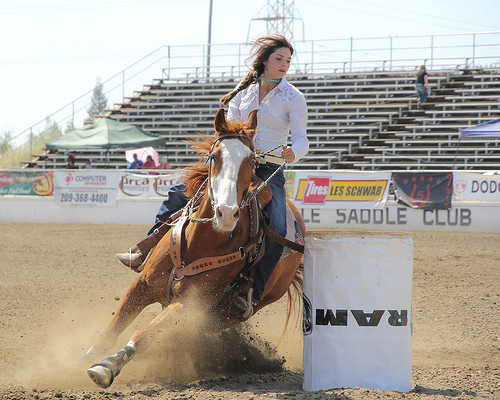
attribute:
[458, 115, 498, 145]
tent — blue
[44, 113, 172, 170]
tent — green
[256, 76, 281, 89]
neck — turqoise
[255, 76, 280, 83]
necklace — green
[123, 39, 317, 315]
jockey — female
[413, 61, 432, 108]
woman — walking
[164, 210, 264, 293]
bridle — brown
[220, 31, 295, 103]
hair — brown, blowing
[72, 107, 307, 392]
horse — big, running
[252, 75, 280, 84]
necklace — turquoise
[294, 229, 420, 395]
sign — white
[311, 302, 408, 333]
writing — black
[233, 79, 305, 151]
shirt — white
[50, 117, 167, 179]
tent — large, green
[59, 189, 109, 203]
number — phone number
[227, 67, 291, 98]
necklace — turquoise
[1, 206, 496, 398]
ground — brown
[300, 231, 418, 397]
barrel — white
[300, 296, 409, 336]
logo — RAM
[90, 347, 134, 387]
straps — black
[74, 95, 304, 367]
horse — brown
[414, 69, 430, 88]
shirt — white